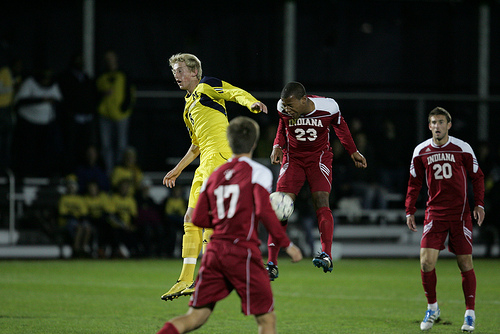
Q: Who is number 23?
A: Soccer player kicking a ball.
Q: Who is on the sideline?
A: Soccer players waiting for their turn.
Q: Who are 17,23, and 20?
A: Three players with red uniforms.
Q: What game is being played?
A: Soccer.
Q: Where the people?
A: On a soccer field.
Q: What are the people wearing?
A: Soccer uniforms.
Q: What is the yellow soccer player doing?
A: Jumping in the air.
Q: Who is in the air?
A: Soccer players.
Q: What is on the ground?
A: Grass.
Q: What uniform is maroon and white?
A: Indiana.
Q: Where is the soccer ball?
A: In the air.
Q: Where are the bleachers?
A: Behind the players.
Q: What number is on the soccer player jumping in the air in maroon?
A: 23.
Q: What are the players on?
A: Field.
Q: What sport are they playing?
A: Soccer.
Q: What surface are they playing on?
A: Astroturf.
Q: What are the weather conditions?
A: Clear and warm.